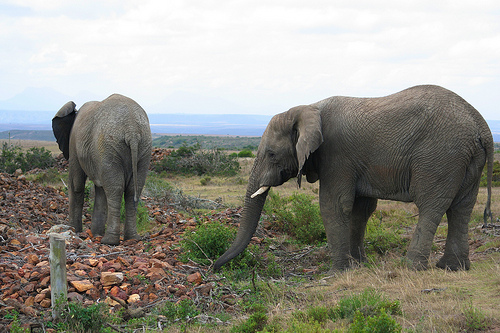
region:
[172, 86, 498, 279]
grey elephant on ground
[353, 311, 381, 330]
green grass on the ground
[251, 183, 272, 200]
the elephant's left tusk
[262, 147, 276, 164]
the elephant's left eye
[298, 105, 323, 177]
the elephant's left ear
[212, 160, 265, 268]
the trunk of the elephant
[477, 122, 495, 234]
the grey elephant's tail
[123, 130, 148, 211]
tail on the elephant in front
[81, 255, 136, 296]
bricks on the ground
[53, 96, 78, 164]
the front elephant's left ear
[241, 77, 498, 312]
an elephant standing in the grass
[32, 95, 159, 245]
an elephant standing in the rocks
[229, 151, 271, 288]
the long trunk of the elephant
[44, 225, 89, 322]
a wooden pole sticking up out of the ground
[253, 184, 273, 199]
the tusk of the elephant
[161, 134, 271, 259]
field filled with brush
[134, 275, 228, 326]
dead twigs lying on the ground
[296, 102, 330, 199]
the elephants ear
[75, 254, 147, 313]
red and golden rocks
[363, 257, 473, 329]
dead grass that is dry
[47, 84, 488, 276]
Two elephant's standing on the field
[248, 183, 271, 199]
Left tusk of the elephant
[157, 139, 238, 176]
Green foliage on the field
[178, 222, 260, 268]
Green shurb near the elephant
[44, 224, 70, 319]
Small post near the elephant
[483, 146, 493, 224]
Tail of the elephant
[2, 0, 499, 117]
Cloudy sky in the back ground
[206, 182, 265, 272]
Trunk of the elephant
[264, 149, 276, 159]
Left eye of the elephant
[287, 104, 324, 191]
Left ear flap of the elephant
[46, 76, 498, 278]
two elephants in a field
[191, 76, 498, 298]
elephant is searching on the ground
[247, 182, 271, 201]
a white tusk of elephant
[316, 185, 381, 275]
front legs of elephant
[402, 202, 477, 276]
back legs of elephant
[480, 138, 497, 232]
the tail of elephant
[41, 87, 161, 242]
the elephant is brown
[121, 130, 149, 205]
the tail of elephant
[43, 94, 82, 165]
left ear of elephant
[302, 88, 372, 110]
a bump on back of elephant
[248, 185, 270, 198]
a white elephant tusk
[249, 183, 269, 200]
the tuck is broken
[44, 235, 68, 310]
a wooden post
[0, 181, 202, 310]
red rocks under the elephant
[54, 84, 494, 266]
two elephants standing together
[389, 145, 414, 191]
wrinkles on the elephant's stomach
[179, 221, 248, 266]
a small green bush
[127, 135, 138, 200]
the elephant's tail is short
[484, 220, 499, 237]
a small pile of sticks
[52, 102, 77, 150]
the ear is standing out